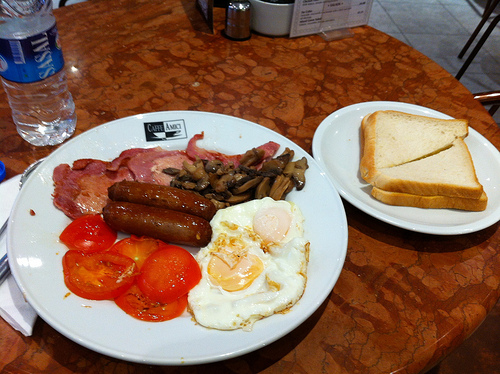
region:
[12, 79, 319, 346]
food on a palte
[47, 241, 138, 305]
red tomatoes on plate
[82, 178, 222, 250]
brown sausage on plate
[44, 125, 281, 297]
food on white plate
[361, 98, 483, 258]
toast on a plate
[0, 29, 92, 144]
plastic water bottle on plate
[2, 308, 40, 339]
white napkin on table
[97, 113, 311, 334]
breakfast food on plate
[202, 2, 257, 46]
salt and pepper shakers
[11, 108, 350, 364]
a large white dinner plate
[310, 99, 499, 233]
a small white dinner plate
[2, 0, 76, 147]
a clear plastic bottle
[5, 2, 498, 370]
a brown marbleized tabletop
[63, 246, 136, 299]
a slice of red tomato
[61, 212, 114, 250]
a slice of red tomato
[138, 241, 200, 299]
a slice of red tomato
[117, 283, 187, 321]
a slice of red tomato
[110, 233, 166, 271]
a slice of red tomato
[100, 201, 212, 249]
a link of sausage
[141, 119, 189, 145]
Black and white graphic on plate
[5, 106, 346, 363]
Breakfast food on a round plate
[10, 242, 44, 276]
Reflection of light on porcelain plate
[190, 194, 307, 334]
Two eggs prepared sunnyside up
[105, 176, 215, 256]
Two sausage links on a plate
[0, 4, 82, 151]
Water bottle on wooden table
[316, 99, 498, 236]
Sliced and halved bread on plate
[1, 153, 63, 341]
White napkin with silverware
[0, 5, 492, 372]
Round table with marbling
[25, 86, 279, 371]
a plate of food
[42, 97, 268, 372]
a white plate of food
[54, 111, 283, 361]
food on a plate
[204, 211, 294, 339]
a cooked egg on plate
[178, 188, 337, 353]
a plate with cooked egg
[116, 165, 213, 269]
sausage on a plate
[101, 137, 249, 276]
sausage on a white plate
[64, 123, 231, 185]
meat on a plate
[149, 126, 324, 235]
green beans on a plate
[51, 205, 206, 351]
tomotas ona plate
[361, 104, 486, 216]
bread slices on plate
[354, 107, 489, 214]
four pieces of bread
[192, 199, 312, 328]
fried eggs on plate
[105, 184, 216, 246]
cooked sausages on plate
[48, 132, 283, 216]
ham slices on plate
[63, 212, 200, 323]
tomato slices on plate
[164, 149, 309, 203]
cooked mushrooms on plate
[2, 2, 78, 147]
bottle of water on table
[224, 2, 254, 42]
pepper shaker on table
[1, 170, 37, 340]
white napkin on table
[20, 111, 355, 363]
a plate of food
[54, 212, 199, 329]
a group of tomatoes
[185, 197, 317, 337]
a pair of eggs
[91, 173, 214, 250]
a pair of sausage